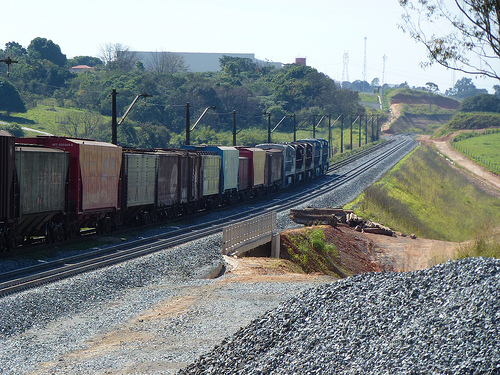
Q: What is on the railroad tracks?
A: Freight cars.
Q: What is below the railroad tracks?
A: Grassy slope.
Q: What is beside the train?
A: Poles and power lines.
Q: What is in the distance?
A: Large building.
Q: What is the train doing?
A: Moving along the tracks.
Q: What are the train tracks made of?
A: Iron,.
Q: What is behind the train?
A: Trees.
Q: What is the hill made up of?
A: Gravel.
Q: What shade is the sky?
A: Pale blue.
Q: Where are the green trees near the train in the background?
A: Near a long fence.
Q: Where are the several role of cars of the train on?
A: The train tracks.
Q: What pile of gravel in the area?
A: Gray gravel on the right.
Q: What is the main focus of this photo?
A: A train.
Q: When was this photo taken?
A: Outside, during the daytime.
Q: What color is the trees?
A: Green.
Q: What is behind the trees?
A: A building.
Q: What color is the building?
A: White.